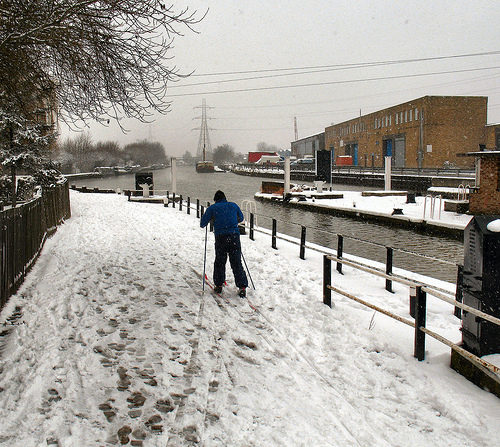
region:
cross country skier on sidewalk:
[150, 175, 280, 350]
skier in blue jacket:
[139, 170, 268, 320]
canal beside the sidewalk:
[247, 188, 489, 296]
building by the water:
[310, 91, 489, 182]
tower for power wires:
[178, 89, 227, 185]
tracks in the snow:
[72, 260, 181, 442]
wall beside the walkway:
[0, 173, 85, 290]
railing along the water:
[164, 188, 431, 291]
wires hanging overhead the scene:
[188, 63, 340, 99]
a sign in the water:
[120, 165, 159, 203]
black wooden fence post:
[412, 285, 427, 360]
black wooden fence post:
[321, 255, 332, 306]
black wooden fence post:
[452, 265, 462, 318]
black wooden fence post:
[384, 248, 393, 292]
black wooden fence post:
[334, 235, 346, 271]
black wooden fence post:
[298, 223, 310, 260]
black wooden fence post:
[271, 214, 281, 251]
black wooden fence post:
[246, 211, 256, 236]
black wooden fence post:
[170, 192, 179, 208]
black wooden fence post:
[185, 196, 195, 214]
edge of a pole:
[418, 335, 445, 355]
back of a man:
[218, 232, 255, 269]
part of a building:
[454, 135, 470, 148]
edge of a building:
[433, 128, 440, 149]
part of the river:
[373, 215, 419, 255]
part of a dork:
[388, 192, 435, 223]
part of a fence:
[21, 195, 30, 240]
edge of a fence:
[24, 189, 26, 208]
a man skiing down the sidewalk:
[182, 188, 267, 310]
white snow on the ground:
[71, 316, 320, 418]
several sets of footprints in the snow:
[92, 303, 167, 430]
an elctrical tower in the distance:
[188, 95, 227, 165]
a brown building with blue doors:
[317, 98, 465, 168]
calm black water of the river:
[161, 173, 248, 188]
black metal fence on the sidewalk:
[267, 213, 429, 283]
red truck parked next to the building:
[243, 149, 279, 160]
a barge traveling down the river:
[193, 145, 219, 177]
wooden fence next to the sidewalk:
[0, 177, 73, 272]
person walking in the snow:
[193, 179, 258, 302]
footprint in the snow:
[92, 399, 118, 424]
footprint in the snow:
[113, 420, 133, 445]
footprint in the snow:
[146, 410, 163, 436]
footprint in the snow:
[128, 425, 148, 445]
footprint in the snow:
[116, 363, 130, 390]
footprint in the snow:
[205, 375, 221, 394]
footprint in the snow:
[180, 381, 197, 398]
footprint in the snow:
[180, 421, 199, 445]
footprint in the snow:
[234, 334, 259, 351]